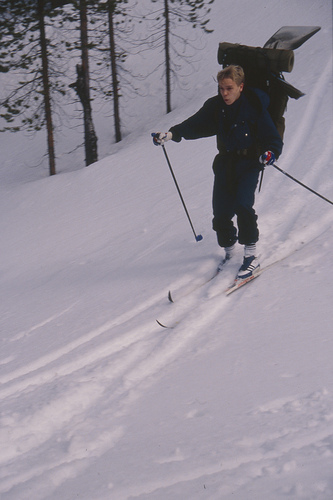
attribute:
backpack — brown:
[218, 26, 321, 143]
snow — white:
[3, 4, 329, 499]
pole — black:
[266, 162, 332, 206]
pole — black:
[160, 145, 204, 242]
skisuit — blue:
[171, 94, 284, 244]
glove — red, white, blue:
[259, 150, 275, 167]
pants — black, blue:
[212, 172, 259, 248]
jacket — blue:
[172, 89, 281, 158]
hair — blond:
[218, 64, 245, 89]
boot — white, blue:
[237, 255, 261, 280]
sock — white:
[241, 243, 255, 259]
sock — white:
[222, 245, 237, 257]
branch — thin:
[3, 76, 40, 102]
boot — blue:
[218, 255, 231, 270]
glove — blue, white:
[152, 132, 170, 148]